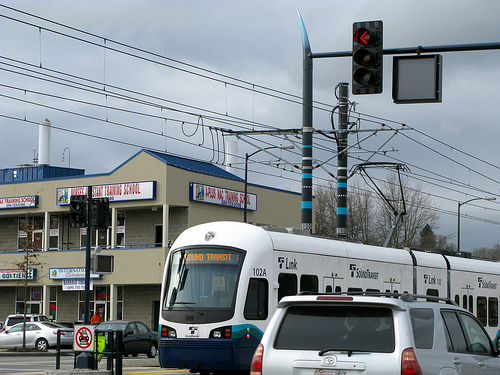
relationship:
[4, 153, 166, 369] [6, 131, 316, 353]
facade of building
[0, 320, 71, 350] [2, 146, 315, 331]
car parked in front of building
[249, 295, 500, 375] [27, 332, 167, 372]
car parked on side of road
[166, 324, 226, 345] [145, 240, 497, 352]
headlights of train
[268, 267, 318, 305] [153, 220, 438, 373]
door of train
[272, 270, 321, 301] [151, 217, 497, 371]
window of train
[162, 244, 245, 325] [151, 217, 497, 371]
windshield of train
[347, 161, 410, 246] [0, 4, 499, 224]
rail connection by overhead wires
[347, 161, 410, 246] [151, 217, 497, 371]
rail connection to train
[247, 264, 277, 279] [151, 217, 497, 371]
id number of a train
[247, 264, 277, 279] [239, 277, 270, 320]
id number above a side window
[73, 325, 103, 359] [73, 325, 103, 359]
sign has a sign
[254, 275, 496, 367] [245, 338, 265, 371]
car has a tail light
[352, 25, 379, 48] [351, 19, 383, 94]
arrow on a traffic light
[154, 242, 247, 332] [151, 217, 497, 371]
windshield on train